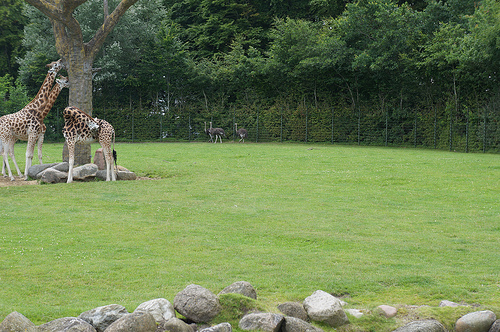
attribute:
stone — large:
[455, 306, 498, 331]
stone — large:
[437, 299, 474, 317]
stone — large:
[301, 290, 347, 322]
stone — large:
[177, 281, 225, 322]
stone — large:
[227, 279, 259, 304]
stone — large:
[134, 295, 177, 332]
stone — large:
[36, 315, 102, 331]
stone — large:
[239, 307, 287, 332]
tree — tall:
[427, 4, 492, 151]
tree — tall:
[385, 3, 435, 149]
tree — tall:
[348, 3, 411, 144]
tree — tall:
[282, 11, 339, 141]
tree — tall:
[179, 0, 258, 143]